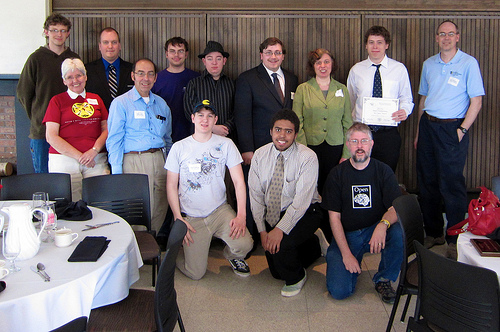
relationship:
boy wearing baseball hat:
[158, 113, 302, 253] [193, 99, 217, 114]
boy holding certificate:
[340, 22, 446, 212] [359, 96, 399, 128]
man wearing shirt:
[316, 121, 406, 304] [324, 160, 406, 229]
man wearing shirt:
[248, 108, 330, 296] [248, 143, 318, 235]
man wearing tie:
[248, 108, 330, 296] [262, 154, 287, 225]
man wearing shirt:
[104, 57, 174, 246] [105, 86, 172, 173]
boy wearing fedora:
[182, 41, 231, 125] [198, 39, 229, 58]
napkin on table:
[63, 233, 110, 265] [0, 193, 144, 330]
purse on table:
[444, 183, 497, 235] [444, 189, 498, 318]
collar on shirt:
[68, 87, 86, 100] [44, 90, 108, 151]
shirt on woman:
[44, 90, 108, 151] [42, 57, 108, 203]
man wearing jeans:
[316, 121, 406, 304] [330, 212, 410, 302]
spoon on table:
[36, 259, 53, 281] [5, 188, 151, 329]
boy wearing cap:
[164, 100, 255, 281] [185, 95, 225, 118]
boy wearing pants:
[164, 100, 255, 281] [178, 208, 256, 275]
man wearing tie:
[240, 110, 317, 292] [266, 147, 286, 227]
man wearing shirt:
[240, 110, 317, 292] [247, 139, 315, 232]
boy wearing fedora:
[183, 40, 237, 212] [197, 40, 229, 59]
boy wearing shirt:
[183, 40, 237, 212] [188, 73, 230, 119]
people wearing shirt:
[292, 48, 354, 197] [38, 91, 108, 160]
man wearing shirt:
[411, 17, 488, 263] [423, 50, 484, 121]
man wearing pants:
[411, 17, 488, 263] [412, 108, 466, 221]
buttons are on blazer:
[317, 100, 333, 137] [291, 76, 353, 158]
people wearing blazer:
[292, 48, 354, 197] [291, 76, 353, 158]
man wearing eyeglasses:
[105, 58, 173, 237] [135, 72, 155, 77]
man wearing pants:
[105, 58, 173, 237] [121, 149, 170, 229]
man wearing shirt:
[105, 58, 173, 237] [99, 88, 181, 173]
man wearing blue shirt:
[84, 27, 133, 114] [102, 60, 122, 97]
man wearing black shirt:
[84, 27, 133, 114] [84, 56, 134, 114]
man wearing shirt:
[311, 117, 425, 316] [324, 160, 406, 229]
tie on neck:
[262, 154, 287, 225] [270, 141, 300, 155]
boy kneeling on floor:
[164, 100, 255, 281] [169, 254, 419, 331]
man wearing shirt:
[105, 58, 173, 237] [98, 87, 155, 147]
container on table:
[1, 204, 49, 261] [0, 193, 155, 320]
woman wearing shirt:
[37, 52, 114, 172] [16, 83, 130, 163]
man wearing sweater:
[9, 4, 96, 158] [17, 44, 68, 116]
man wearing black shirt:
[76, 22, 136, 94] [84, 56, 134, 114]